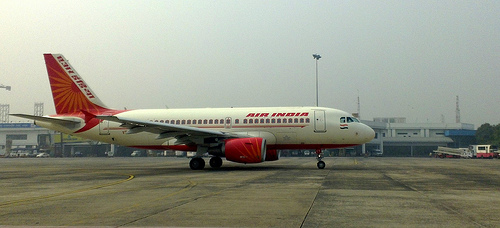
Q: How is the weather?
A: It is overcast.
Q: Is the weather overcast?
A: Yes, it is overcast.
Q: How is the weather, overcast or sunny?
A: It is overcast.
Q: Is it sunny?
A: No, it is overcast.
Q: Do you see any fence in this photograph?
A: No, there are no fences.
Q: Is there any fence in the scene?
A: No, there are no fences.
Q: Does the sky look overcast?
A: Yes, the sky is overcast.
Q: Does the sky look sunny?
A: No, the sky is overcast.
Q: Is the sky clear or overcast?
A: The sky is overcast.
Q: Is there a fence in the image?
A: No, there are no fences.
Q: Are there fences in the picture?
A: No, there are no fences.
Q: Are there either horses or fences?
A: No, there are no fences or horses.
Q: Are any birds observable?
A: No, there are no birds.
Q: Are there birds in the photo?
A: No, there are no birds.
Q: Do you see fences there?
A: No, there are no fences.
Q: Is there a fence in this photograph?
A: No, there are no fences.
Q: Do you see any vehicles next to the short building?
A: Yes, there is a vehicle next to the building.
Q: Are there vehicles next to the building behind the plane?
A: Yes, there is a vehicle next to the building.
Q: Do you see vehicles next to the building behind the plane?
A: Yes, there is a vehicle next to the building.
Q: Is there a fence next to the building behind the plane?
A: No, there is a vehicle next to the building.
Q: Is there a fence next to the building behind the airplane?
A: No, there is a vehicle next to the building.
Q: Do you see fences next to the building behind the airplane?
A: No, there is a vehicle next to the building.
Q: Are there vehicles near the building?
A: Yes, there is a vehicle near the building.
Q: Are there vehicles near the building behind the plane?
A: Yes, there is a vehicle near the building.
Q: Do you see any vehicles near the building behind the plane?
A: Yes, there is a vehicle near the building.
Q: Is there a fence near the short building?
A: No, there is a vehicle near the building.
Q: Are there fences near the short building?
A: No, there is a vehicle near the building.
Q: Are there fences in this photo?
A: No, there are no fences.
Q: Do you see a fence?
A: No, there are no fences.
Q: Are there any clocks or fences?
A: No, there are no fences or clocks.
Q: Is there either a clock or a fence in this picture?
A: No, there are no fences or clocks.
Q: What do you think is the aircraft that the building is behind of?
A: The aircraft is an airplane.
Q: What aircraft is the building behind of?
A: The building is behind the airplane.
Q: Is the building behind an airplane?
A: Yes, the building is behind an airplane.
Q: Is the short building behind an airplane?
A: Yes, the building is behind an airplane.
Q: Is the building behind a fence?
A: No, the building is behind an airplane.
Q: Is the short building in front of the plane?
A: No, the building is behind the plane.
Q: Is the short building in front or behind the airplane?
A: The building is behind the airplane.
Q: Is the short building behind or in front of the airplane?
A: The building is behind the airplane.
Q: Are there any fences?
A: No, there are no fences.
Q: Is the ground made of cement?
A: Yes, the ground is made of cement.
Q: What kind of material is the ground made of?
A: The ground is made of cement.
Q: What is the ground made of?
A: The ground is made of concrete.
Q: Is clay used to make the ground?
A: No, the ground is made of concrete.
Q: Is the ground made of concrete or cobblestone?
A: The ground is made of concrete.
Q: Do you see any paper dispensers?
A: No, there are no paper dispensers.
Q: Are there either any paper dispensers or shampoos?
A: No, there are no paper dispensers or shampoos.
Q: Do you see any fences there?
A: No, there are no fences.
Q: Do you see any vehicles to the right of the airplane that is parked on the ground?
A: Yes, there is a vehicle to the right of the airplane.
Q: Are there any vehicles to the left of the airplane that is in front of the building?
A: No, the vehicle is to the right of the plane.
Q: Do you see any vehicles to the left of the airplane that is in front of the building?
A: No, the vehicle is to the right of the plane.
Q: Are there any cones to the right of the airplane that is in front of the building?
A: No, there is a vehicle to the right of the airplane.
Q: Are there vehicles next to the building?
A: Yes, there is a vehicle next to the building.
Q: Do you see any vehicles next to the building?
A: Yes, there is a vehicle next to the building.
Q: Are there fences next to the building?
A: No, there is a vehicle next to the building.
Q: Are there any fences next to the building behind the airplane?
A: No, there is a vehicle next to the building.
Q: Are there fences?
A: No, there are no fences.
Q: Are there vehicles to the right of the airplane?
A: Yes, there is a vehicle to the right of the airplane.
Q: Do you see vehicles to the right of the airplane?
A: Yes, there is a vehicle to the right of the airplane.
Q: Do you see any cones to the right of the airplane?
A: No, there is a vehicle to the right of the airplane.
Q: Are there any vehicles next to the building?
A: Yes, there is a vehicle next to the building.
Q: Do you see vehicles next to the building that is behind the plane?
A: Yes, there is a vehicle next to the building.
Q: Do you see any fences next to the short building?
A: No, there is a vehicle next to the building.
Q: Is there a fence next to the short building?
A: No, there is a vehicle next to the building.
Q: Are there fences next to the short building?
A: No, there is a vehicle next to the building.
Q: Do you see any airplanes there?
A: Yes, there is an airplane.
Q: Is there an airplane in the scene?
A: Yes, there is an airplane.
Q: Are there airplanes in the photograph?
A: Yes, there is an airplane.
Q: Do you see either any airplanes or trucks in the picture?
A: Yes, there is an airplane.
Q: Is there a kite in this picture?
A: No, there are no kites.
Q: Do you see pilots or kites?
A: No, there are no kites or pilots.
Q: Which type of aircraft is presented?
A: The aircraft is an airplane.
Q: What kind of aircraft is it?
A: The aircraft is an airplane.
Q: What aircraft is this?
A: This is an airplane.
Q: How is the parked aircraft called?
A: The aircraft is an airplane.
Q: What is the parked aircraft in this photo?
A: The aircraft is an airplane.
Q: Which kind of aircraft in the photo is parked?
A: The aircraft is an airplane.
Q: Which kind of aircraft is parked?
A: The aircraft is an airplane.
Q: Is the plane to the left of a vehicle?
A: Yes, the plane is to the left of a vehicle.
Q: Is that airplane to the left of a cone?
A: No, the airplane is to the left of a vehicle.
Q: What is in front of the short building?
A: The plane is in front of the building.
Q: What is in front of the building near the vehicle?
A: The plane is in front of the building.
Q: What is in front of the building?
A: The plane is in front of the building.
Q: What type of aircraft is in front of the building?
A: The aircraft is an airplane.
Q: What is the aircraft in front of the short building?
A: The aircraft is an airplane.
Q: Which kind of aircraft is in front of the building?
A: The aircraft is an airplane.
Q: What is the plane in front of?
A: The plane is in front of the building.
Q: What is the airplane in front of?
A: The plane is in front of the building.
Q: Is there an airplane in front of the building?
A: Yes, there is an airplane in front of the building.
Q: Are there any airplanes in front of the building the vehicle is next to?
A: Yes, there is an airplane in front of the building.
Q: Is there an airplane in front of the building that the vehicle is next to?
A: Yes, there is an airplane in front of the building.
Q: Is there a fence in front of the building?
A: No, there is an airplane in front of the building.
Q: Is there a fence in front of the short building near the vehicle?
A: No, there is an airplane in front of the building.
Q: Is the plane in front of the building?
A: Yes, the plane is in front of the building.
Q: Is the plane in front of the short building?
A: Yes, the plane is in front of the building.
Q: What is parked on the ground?
A: The airplane is parked on the ground.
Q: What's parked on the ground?
A: The airplane is parked on the ground.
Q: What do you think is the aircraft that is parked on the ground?
A: The aircraft is an airplane.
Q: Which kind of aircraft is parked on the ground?
A: The aircraft is an airplane.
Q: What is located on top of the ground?
A: The airplane is on top of the ground.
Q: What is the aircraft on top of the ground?
A: The aircraft is an airplane.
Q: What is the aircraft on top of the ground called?
A: The aircraft is an airplane.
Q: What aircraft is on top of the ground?
A: The aircraft is an airplane.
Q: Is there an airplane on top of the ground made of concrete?
A: Yes, there is an airplane on top of the ground.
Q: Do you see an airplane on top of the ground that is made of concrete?
A: Yes, there is an airplane on top of the ground.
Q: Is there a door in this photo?
A: Yes, there is a door.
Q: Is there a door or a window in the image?
A: Yes, there is a door.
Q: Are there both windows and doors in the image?
A: Yes, there are both a door and a window.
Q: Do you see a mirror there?
A: No, there are no mirrors.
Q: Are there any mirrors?
A: No, there are no mirrors.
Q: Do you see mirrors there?
A: No, there are no mirrors.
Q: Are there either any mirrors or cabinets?
A: No, there are no mirrors or cabinets.